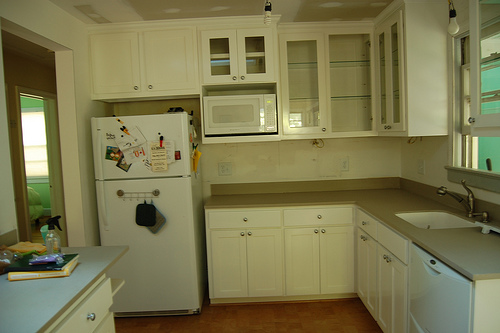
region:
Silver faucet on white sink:
[435, 173, 480, 219]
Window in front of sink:
[452, 23, 498, 186]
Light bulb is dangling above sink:
[442, 0, 461, 37]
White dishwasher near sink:
[397, 238, 476, 331]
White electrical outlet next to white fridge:
[214, 157, 234, 181]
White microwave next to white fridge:
[200, 92, 279, 139]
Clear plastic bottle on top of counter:
[45, 208, 67, 255]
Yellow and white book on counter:
[0, 253, 80, 279]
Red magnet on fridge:
[155, 133, 166, 148]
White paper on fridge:
[111, 121, 146, 151]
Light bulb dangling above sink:
[443, 5, 462, 33]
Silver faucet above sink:
[435, 171, 489, 220]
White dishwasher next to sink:
[400, 236, 478, 331]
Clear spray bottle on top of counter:
[42, 210, 68, 259]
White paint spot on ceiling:
[202, 3, 230, 15]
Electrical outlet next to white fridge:
[218, 153, 234, 177]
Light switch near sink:
[412, 155, 428, 178]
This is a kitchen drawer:
[207, 207, 284, 306]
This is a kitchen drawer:
[284, 201, 356, 299]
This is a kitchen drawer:
[355, 202, 380, 330]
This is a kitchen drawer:
[375, 220, 410, 329]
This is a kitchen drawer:
[275, 23, 370, 138]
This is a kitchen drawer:
[370, 16, 407, 138]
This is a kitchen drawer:
[203, 16, 275, 79]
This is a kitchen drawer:
[137, 28, 204, 86]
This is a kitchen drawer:
[91, 28, 141, 93]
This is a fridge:
[90, 117, 204, 315]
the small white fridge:
[80, 105, 212, 321]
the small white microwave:
[197, 89, 282, 141]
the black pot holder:
[131, 190, 158, 233]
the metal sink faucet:
[417, 170, 494, 232]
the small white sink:
[367, 191, 479, 253]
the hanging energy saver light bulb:
[257, 5, 297, 41]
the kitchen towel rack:
[113, 180, 165, 202]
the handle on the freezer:
[92, 129, 119, 181]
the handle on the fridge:
[95, 183, 127, 234]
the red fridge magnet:
[155, 133, 170, 152]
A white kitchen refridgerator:
[89, 111, 206, 316]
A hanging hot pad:
[135, 199, 156, 229]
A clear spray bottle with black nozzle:
[46, 215, 62, 252]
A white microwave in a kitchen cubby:
[198, 82, 280, 139]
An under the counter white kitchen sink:
[395, 208, 482, 236]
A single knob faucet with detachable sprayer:
[434, 177, 477, 222]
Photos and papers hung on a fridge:
[105, 124, 182, 174]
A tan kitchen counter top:
[203, 176, 498, 330]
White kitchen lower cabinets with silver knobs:
[203, 204, 408, 332]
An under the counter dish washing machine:
[409, 239, 499, 332]